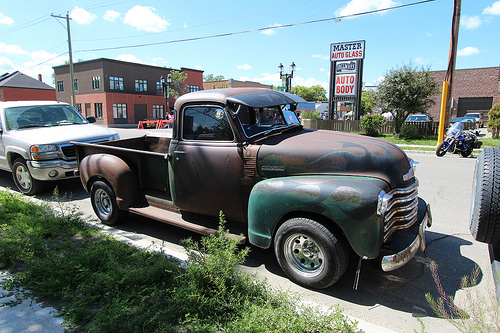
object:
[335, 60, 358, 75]
sign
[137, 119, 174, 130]
sign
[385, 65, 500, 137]
building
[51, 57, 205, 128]
building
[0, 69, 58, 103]
building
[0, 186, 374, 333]
grass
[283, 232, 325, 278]
spokes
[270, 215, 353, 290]
wheel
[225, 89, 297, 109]
visor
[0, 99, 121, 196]
vehicle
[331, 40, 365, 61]
sign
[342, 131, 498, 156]
sidewalk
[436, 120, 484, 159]
motorcycle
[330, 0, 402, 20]
cloud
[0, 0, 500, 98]
sky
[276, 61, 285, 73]
street lights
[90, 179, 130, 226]
wheel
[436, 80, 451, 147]
post side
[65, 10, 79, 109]
telephone pole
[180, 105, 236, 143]
window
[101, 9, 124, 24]
clouds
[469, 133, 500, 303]
truck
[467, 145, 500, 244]
tire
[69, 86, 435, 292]
vehicle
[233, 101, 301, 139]
windshield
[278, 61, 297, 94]
pole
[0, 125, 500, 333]
road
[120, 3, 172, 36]
cloads